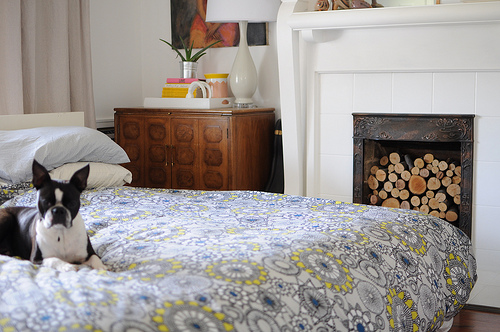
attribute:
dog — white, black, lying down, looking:
[1, 158, 108, 273]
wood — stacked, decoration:
[369, 151, 461, 221]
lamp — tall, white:
[205, 0, 280, 108]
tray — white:
[142, 81, 234, 110]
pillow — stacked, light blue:
[1, 128, 132, 183]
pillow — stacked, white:
[49, 160, 131, 187]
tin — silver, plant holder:
[184, 60, 195, 78]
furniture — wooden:
[115, 109, 275, 188]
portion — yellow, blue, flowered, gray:
[0, 187, 478, 331]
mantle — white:
[277, 0, 499, 28]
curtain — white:
[0, 0, 100, 131]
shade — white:
[205, 0, 283, 22]